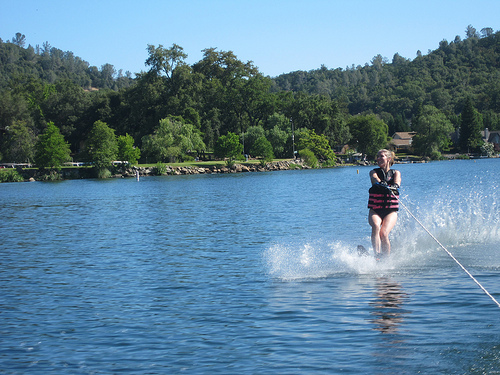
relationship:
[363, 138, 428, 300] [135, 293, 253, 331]
woman on lake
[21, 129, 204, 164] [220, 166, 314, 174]
small trees along shoreline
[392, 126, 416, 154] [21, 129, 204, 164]
house behind small trees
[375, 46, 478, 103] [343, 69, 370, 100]
mountains have trees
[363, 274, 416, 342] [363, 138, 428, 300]
reflection of woman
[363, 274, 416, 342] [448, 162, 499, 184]
reflection in water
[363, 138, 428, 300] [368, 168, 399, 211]
woman in black bathing suit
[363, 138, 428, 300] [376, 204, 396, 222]
woman in black bathing suit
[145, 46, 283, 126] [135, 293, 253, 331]
trees around lake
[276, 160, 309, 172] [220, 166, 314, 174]
rocks on shoreline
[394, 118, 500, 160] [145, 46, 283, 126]
houses surrounded by trees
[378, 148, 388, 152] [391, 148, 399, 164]
hair in bun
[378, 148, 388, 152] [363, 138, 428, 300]
hair of woman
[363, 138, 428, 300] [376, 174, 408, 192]
woman wearing black gloves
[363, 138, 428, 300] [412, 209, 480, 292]
woman holding tether line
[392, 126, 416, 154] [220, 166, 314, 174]
house on shoreline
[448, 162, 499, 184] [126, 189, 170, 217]
water has ripples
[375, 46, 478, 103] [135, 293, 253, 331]
mountains near lake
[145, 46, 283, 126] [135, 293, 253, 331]
trees near lake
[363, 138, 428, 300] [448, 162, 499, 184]
woman in water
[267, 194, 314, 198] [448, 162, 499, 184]
part of water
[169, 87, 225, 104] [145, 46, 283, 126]
part of trees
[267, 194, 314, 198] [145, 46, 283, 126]
part of trees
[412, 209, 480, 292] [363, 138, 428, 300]
tether line held by woman